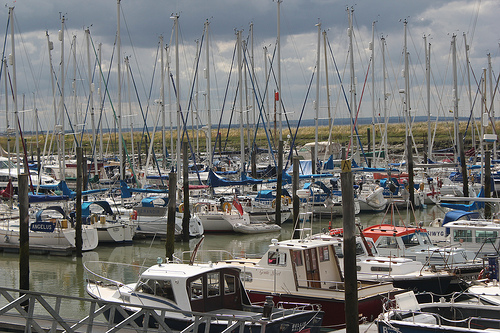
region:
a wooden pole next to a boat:
[333, 157, 369, 331]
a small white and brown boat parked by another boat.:
[81, 257, 314, 326]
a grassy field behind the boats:
[11, 118, 499, 149]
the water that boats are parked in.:
[1, 225, 256, 295]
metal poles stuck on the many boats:
[42, 70, 194, 161]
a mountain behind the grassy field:
[293, 112, 469, 122]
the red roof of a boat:
[358, 219, 426, 244]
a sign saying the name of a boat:
[28, 216, 56, 235]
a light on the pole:
[478, 129, 498, 153]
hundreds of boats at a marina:
[5, 8, 490, 325]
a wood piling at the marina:
[323, 169, 371, 324]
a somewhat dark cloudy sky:
[296, 13, 456, 80]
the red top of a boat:
[368, 217, 421, 241]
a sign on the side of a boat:
[31, 218, 58, 236]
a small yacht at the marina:
[77, 256, 324, 331]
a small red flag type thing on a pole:
[269, 86, 285, 109]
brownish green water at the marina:
[37, 255, 148, 286]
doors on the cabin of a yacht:
[304, 246, 324, 289]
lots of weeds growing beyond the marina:
[286, 122, 402, 139]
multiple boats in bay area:
[4, 129, 498, 331]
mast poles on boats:
[6, 17, 491, 168]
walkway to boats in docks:
[6, 272, 298, 330]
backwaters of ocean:
[8, 227, 355, 297]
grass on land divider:
[5, 117, 498, 146]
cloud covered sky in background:
[10, 23, 491, 116]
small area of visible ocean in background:
[1, 112, 498, 137]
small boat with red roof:
[361, 220, 483, 275]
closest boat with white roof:
[83, 256, 327, 331]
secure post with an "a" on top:
[333, 150, 367, 332]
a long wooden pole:
[337, 156, 367, 328]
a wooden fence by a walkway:
[7, 290, 262, 330]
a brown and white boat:
[83, 263, 325, 330]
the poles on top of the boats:
[129, 70, 493, 182]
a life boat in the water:
[239, 219, 289, 234]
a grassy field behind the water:
[7, 111, 499, 151]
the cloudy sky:
[40, 72, 275, 128]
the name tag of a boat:
[30, 219, 66, 239]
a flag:
[223, 196, 245, 216]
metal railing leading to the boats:
[1, 286, 273, 331]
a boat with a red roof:
[365, 220, 489, 277]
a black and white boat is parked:
[83, 260, 323, 328]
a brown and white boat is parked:
[208, 234, 394, 324]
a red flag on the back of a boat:
[230, 191, 250, 219]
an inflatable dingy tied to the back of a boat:
[231, 221, 282, 234]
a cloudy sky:
[0, 4, 499, 127]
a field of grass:
[0, 120, 499, 151]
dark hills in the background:
[1, 113, 499, 134]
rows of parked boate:
[7, 5, 499, 250]